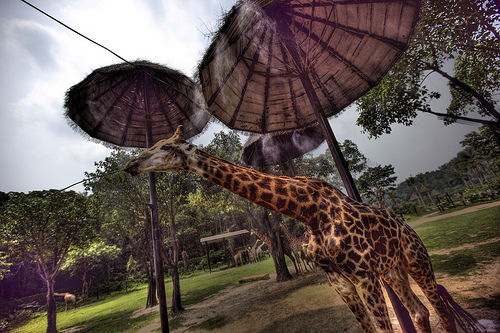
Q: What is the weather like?
A: It is cloudy.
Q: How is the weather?
A: It is cloudy.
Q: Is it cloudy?
A: Yes, it is cloudy.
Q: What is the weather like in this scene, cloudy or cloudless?
A: It is cloudy.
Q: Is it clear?
A: No, it is cloudy.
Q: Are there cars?
A: No, there are no cars.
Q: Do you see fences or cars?
A: No, there are no cars or fences.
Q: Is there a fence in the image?
A: No, there are no fences.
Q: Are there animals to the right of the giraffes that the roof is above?
A: Yes, there are animals to the right of the giraffes.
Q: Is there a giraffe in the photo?
A: Yes, there is a giraffe.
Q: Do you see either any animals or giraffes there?
A: Yes, there is a giraffe.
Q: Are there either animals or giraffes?
A: Yes, there is a giraffe.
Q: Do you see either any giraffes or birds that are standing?
A: Yes, the giraffe is standing.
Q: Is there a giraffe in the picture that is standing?
A: Yes, there is a giraffe that is standing.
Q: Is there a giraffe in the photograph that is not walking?
A: Yes, there is a giraffe that is standing.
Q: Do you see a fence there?
A: No, there are no fences.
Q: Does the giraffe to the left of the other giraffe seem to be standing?
A: Yes, the giraffe is standing.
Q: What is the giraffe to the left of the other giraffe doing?
A: The giraffe is standing.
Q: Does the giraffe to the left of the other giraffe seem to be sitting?
A: No, the giraffe is standing.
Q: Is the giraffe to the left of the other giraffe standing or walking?
A: The giraffe is standing.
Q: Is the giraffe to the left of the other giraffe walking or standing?
A: The giraffe is standing.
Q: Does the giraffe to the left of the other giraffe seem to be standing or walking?
A: The giraffe is standing.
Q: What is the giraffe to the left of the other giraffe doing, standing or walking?
A: The giraffe is standing.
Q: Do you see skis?
A: No, there are no skis.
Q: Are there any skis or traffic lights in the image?
A: No, there are no skis or traffic lights.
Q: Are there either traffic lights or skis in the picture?
A: No, there are no skis or traffic lights.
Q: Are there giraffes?
A: Yes, there is a giraffe.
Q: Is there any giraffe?
A: Yes, there is a giraffe.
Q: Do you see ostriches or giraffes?
A: Yes, there is a giraffe.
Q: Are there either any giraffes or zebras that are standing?
A: Yes, the giraffe is standing.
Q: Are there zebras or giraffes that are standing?
A: Yes, the giraffe is standing.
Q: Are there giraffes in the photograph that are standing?
A: Yes, there is a giraffe that is standing.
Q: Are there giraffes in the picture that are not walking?
A: Yes, there is a giraffe that is standing.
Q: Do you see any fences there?
A: No, there are no fences.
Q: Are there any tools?
A: No, there are no tools.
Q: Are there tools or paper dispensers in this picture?
A: No, there are no tools or paper dispensers.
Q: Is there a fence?
A: No, there are no fences.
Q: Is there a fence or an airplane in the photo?
A: No, there are no fences or airplanes.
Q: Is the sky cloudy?
A: Yes, the sky is cloudy.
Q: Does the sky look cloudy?
A: Yes, the sky is cloudy.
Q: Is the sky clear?
A: No, the sky is cloudy.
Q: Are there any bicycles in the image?
A: No, there are no bicycles.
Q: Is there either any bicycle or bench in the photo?
A: No, there are no bicycles or benches.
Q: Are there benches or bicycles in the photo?
A: No, there are no bicycles or benches.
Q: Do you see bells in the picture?
A: No, there are no bells.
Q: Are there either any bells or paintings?
A: No, there are no bells or paintings.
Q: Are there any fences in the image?
A: No, there are no fences.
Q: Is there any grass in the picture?
A: Yes, there is grass.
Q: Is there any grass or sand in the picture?
A: Yes, there is grass.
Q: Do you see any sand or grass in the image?
A: Yes, there is grass.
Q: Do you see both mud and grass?
A: No, there is grass but no mud.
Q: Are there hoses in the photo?
A: No, there are no hoses.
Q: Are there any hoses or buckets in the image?
A: No, there are no hoses or buckets.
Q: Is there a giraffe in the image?
A: Yes, there is a giraffe.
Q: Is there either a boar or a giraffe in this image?
A: Yes, there is a giraffe.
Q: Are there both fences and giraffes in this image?
A: No, there is a giraffe but no fences.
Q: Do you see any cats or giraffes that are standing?
A: Yes, the giraffe is standing.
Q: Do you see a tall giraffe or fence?
A: Yes, there is a tall giraffe.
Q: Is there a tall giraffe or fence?
A: Yes, there is a tall giraffe.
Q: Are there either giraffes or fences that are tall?
A: Yes, the giraffe is tall.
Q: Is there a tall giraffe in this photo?
A: Yes, there is a tall giraffe.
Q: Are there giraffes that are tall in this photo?
A: Yes, there is a tall giraffe.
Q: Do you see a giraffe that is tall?
A: Yes, there is a giraffe that is tall.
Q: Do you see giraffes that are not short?
A: Yes, there is a tall giraffe.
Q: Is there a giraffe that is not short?
A: Yes, there is a tall giraffe.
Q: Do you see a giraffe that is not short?
A: Yes, there is a tall giraffe.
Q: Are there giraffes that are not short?
A: Yes, there is a tall giraffe.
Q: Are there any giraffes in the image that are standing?
A: Yes, there is a giraffe that is standing.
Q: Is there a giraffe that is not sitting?
A: Yes, there is a giraffe that is standing.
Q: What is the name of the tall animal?
A: The animal is a giraffe.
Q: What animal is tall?
A: The animal is a giraffe.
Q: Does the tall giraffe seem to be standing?
A: Yes, the giraffe is standing.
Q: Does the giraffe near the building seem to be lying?
A: No, the giraffe is standing.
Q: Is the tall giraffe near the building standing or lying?
A: The giraffe is standing.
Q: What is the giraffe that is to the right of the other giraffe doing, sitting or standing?
A: The giraffe is standing.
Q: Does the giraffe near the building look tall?
A: Yes, the giraffe is tall.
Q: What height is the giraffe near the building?
A: The giraffe is tall.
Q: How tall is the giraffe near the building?
A: The giraffe is tall.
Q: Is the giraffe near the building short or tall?
A: The giraffe is tall.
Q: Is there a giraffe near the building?
A: Yes, there is a giraffe near the building.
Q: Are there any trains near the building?
A: No, there is a giraffe near the building.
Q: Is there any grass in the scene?
A: Yes, there is grass.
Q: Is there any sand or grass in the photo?
A: Yes, there is grass.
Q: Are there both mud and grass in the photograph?
A: No, there is grass but no mud.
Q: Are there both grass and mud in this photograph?
A: No, there is grass but no mud.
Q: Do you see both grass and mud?
A: No, there is grass but no mud.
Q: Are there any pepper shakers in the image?
A: No, there are no pepper shakers.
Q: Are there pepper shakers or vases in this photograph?
A: No, there are no pepper shakers or vases.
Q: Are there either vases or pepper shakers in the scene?
A: No, there are no pepper shakers or vases.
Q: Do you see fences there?
A: No, there are no fences.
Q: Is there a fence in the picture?
A: No, there are no fences.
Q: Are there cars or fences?
A: No, there are no fences or cars.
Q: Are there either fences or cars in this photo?
A: No, there are no fences or cars.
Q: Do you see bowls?
A: No, there are no bowls.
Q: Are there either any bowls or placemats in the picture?
A: No, there are no bowls or placemats.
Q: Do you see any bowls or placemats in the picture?
A: No, there are no bowls or placemats.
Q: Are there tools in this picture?
A: No, there are no tools.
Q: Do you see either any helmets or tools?
A: No, there are no tools or helmets.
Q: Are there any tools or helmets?
A: No, there are no tools or helmets.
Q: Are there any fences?
A: No, there are no fences.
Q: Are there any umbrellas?
A: Yes, there is an umbrella.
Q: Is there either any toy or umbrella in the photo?
A: Yes, there is an umbrella.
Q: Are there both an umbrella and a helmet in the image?
A: No, there is an umbrella but no helmets.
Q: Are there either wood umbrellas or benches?
A: Yes, there is a wood umbrella.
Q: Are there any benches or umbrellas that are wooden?
A: Yes, the umbrella is wooden.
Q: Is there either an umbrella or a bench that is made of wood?
A: Yes, the umbrella is made of wood.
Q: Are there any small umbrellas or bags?
A: Yes, there is a small umbrella.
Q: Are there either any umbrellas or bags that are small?
A: Yes, the umbrella is small.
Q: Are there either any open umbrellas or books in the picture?
A: Yes, there is an open umbrella.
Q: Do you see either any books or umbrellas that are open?
A: Yes, the umbrella is open.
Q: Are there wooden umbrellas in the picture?
A: Yes, there is a wood umbrella.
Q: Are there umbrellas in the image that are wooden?
A: Yes, there is an umbrella that is wooden.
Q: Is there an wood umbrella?
A: Yes, there is an umbrella that is made of wood.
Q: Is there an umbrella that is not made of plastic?
A: Yes, there is an umbrella that is made of wood.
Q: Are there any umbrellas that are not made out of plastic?
A: Yes, there is an umbrella that is made of wood.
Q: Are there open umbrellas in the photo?
A: Yes, there is an open umbrella.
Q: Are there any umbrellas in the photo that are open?
A: Yes, there is an umbrella that is open.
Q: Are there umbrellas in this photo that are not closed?
A: Yes, there is a open umbrella.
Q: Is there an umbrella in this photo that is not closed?
A: Yes, there is a open umbrella.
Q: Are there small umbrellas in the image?
A: Yes, there is a small umbrella.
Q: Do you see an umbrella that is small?
A: Yes, there is an umbrella that is small.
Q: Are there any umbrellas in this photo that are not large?
A: Yes, there is a small umbrella.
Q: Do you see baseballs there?
A: No, there are no baseballs.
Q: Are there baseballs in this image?
A: No, there are no baseballs.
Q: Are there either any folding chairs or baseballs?
A: No, there are no baseballs or folding chairs.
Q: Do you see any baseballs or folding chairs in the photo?
A: No, there are no baseballs or folding chairs.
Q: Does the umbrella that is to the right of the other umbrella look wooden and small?
A: Yes, the umbrella is wooden and small.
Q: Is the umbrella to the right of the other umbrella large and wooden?
A: No, the umbrella is wooden but small.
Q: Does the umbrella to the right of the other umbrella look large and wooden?
A: No, the umbrella is wooden but small.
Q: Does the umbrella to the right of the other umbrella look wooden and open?
A: Yes, the umbrella is wooden and open.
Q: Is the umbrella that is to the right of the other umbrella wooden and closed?
A: No, the umbrella is wooden but open.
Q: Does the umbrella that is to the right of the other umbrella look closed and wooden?
A: No, the umbrella is wooden but open.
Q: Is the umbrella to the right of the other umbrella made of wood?
A: Yes, the umbrella is made of wood.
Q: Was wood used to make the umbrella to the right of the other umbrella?
A: Yes, the umbrella is made of wood.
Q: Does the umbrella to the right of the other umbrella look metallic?
A: No, the umbrella is wooden.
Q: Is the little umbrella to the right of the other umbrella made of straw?
A: No, the umbrella is made of wood.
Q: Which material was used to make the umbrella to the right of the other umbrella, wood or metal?
A: The umbrella is made of wood.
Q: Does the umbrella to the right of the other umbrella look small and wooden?
A: Yes, the umbrella is small and wooden.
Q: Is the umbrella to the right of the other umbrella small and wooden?
A: Yes, the umbrella is small and wooden.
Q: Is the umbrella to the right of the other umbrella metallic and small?
A: No, the umbrella is small but wooden.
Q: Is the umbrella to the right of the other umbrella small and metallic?
A: No, the umbrella is small but wooden.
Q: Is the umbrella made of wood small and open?
A: Yes, the umbrella is small and open.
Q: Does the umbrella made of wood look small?
A: Yes, the umbrella is small.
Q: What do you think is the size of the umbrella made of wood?
A: The umbrella is small.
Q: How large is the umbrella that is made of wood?
A: The umbrella is small.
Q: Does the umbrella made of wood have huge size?
A: No, the umbrella is small.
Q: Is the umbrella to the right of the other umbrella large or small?
A: The umbrella is small.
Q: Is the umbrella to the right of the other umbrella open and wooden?
A: Yes, the umbrella is open and wooden.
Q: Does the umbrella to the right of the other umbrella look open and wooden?
A: Yes, the umbrella is open and wooden.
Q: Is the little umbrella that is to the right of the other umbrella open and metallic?
A: No, the umbrella is open but wooden.